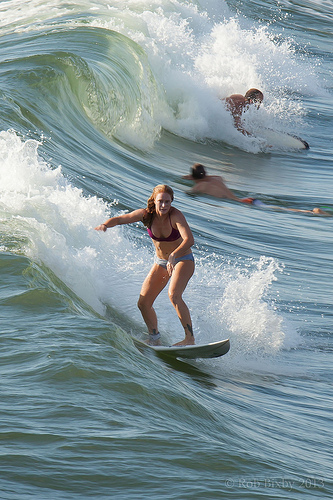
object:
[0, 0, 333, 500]
wave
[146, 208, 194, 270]
bikini top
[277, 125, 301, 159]
ground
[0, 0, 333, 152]
ocean waves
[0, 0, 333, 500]
ocean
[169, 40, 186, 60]
ground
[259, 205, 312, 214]
surfboard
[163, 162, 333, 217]
man swimming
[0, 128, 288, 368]
foam waves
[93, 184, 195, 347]
girl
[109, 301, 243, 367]
surfboard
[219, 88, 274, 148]
person